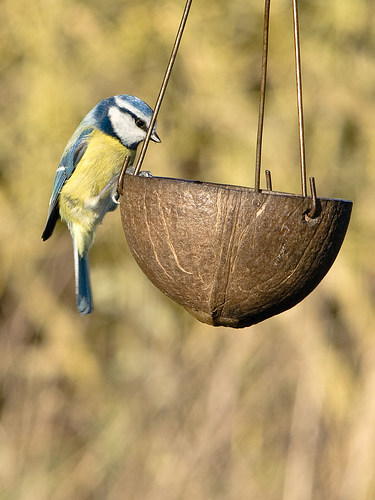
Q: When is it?
A: Day time.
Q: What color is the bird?
A: Blue and yellow.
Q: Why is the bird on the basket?
A: Looking for food.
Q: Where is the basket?
A: Hanging.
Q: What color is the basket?
A: Brown.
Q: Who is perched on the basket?
A: A bird.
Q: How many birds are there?
A: One.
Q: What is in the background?
A: Grass.